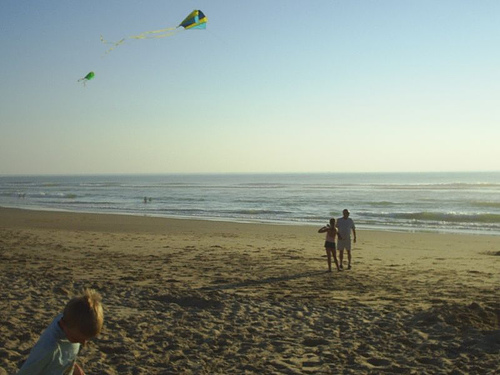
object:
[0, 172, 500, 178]
line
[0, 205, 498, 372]
sand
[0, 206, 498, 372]
beach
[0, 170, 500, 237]
ocean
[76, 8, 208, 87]
kites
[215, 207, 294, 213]
waves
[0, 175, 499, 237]
waves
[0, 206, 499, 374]
shore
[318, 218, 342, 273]
person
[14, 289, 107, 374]
person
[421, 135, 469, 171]
ground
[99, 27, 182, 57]
tail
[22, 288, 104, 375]
boy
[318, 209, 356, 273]
people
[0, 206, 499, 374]
ground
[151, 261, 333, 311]
shadow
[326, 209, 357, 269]
people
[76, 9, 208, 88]
kite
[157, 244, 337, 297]
shadow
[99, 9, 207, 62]
kite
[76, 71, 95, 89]
kite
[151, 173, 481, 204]
water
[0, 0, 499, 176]
sky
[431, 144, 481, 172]
lightest part